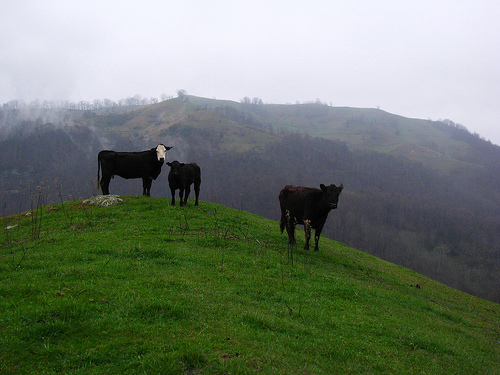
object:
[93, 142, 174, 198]
cow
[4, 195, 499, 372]
mountain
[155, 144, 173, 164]
face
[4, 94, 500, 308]
mountain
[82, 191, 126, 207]
rock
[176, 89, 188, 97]
tree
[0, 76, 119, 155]
fog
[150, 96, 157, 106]
tree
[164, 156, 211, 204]
cow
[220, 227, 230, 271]
stick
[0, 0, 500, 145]
sky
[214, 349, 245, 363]
dirt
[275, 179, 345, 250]
cow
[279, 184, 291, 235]
tail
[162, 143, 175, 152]
ear